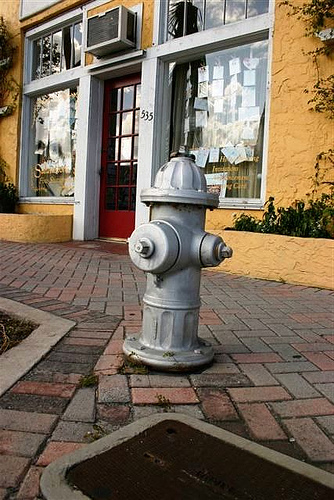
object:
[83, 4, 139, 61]
ac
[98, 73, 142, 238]
door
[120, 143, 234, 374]
hydrant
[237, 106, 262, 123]
picture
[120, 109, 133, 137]
window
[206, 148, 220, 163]
picture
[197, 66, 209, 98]
picture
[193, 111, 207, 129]
picture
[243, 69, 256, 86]
picture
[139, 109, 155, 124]
535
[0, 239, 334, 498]
sidewalk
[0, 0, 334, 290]
building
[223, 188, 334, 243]
plants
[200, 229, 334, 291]
planter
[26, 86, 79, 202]
window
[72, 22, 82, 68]
window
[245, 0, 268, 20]
window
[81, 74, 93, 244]
trim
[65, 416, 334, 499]
grate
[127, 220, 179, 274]
cap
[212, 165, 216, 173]
letters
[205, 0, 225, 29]
panel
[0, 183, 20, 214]
plant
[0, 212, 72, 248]
planter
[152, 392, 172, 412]
grass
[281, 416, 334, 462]
brick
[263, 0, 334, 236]
wall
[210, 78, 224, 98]
picture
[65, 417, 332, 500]
sewer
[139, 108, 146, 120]
number